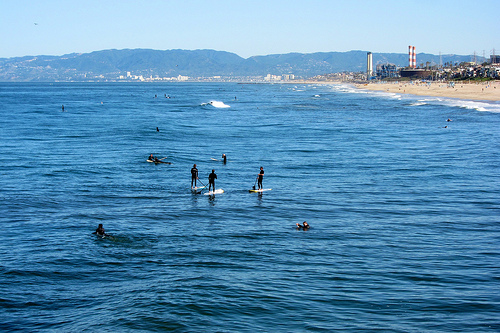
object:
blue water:
[0, 81, 500, 332]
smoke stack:
[410, 45, 416, 67]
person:
[59, 103, 65, 109]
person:
[95, 221, 105, 238]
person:
[156, 125, 160, 132]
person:
[445, 116, 454, 121]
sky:
[1, 0, 500, 59]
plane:
[32, 21, 40, 27]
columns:
[406, 44, 414, 66]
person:
[294, 219, 309, 231]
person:
[206, 167, 218, 192]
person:
[219, 152, 230, 164]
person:
[255, 164, 265, 191]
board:
[246, 187, 274, 193]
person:
[190, 162, 200, 185]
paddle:
[198, 177, 208, 188]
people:
[479, 88, 484, 93]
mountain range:
[0, 48, 492, 83]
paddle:
[252, 178, 259, 189]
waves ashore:
[333, 84, 402, 99]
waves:
[410, 96, 499, 114]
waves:
[203, 100, 232, 108]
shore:
[290, 81, 500, 102]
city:
[116, 47, 500, 83]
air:
[4, 0, 55, 42]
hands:
[256, 172, 259, 175]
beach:
[291, 80, 499, 103]